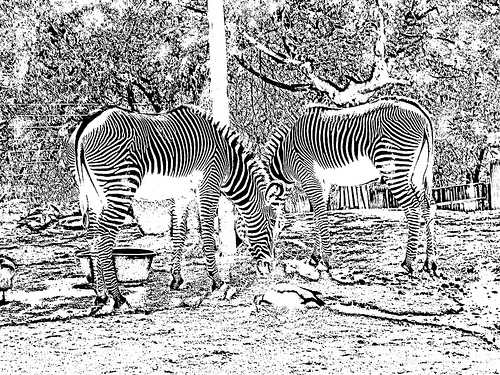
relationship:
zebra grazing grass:
[65, 97, 282, 310] [0, 210, 499, 372]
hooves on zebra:
[84, 287, 136, 319] [65, 97, 282, 310]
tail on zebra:
[424, 135, 439, 196] [252, 92, 441, 275]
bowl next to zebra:
[78, 247, 153, 285] [65, 97, 282, 310]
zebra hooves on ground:
[387, 244, 457, 283] [222, 287, 392, 354]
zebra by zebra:
[252, 92, 441, 275] [60, 89, 290, 314]